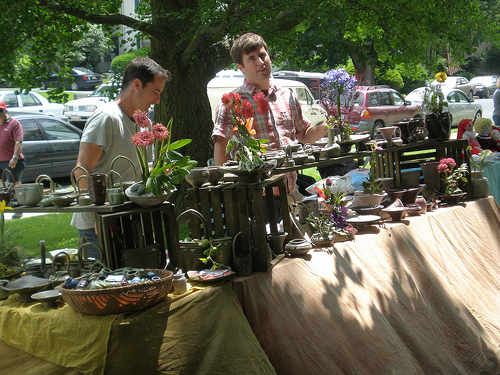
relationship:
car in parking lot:
[8, 108, 85, 183] [0, 43, 492, 141]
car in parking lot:
[0, 87, 64, 119] [0, 72, 120, 182]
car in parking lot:
[0, 87, 64, 119] [1, 105, 91, 192]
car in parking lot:
[410, 83, 484, 124] [2, 68, 497, 189]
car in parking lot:
[0, 87, 64, 119] [2, 68, 497, 189]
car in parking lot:
[8, 108, 85, 183] [2, 68, 497, 189]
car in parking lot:
[321, 73, 417, 140] [2, 68, 497, 189]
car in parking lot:
[410, 83, 484, 124] [342, 82, 499, 130]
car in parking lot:
[311, 52, 463, 185] [310, 79, 498, 129]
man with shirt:
[206, 30, 330, 230] [223, 31, 319, 149]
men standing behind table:
[69, 34, 331, 259] [15, 190, 478, 367]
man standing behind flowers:
[72, 53, 170, 227] [201, 88, 398, 168]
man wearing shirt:
[72, 53, 170, 227] [83, 107, 165, 229]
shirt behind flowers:
[83, 107, 165, 229] [121, 107, 178, 169]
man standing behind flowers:
[206, 30, 330, 230] [221, 66, 361, 170]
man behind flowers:
[206, 30, 330, 230] [225, 88, 259, 163]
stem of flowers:
[335, 114, 351, 151] [310, 60, 365, 142]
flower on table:
[219, 93, 266, 144] [15, 190, 478, 367]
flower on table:
[219, 93, 266, 144] [262, 150, 479, 252]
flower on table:
[318, 63, 363, 138] [26, 147, 397, 285]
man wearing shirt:
[206, 30, 330, 230] [206, 82, 306, 183]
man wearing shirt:
[72, 53, 170, 227] [68, 102, 153, 225]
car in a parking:
[321, 73, 417, 140] [326, 57, 416, 134]